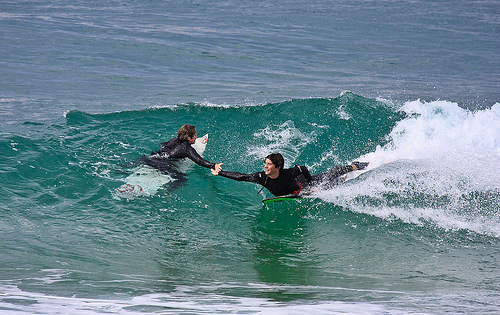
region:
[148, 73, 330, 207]
Surfers high fiving.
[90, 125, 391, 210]
Two surfers passing each other.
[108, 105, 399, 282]
Surfers on the waves.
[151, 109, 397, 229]
Surfer smiling in the water.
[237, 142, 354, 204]
Surfer in a black wet suit.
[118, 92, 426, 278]
Surfer on a wave.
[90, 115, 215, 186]
Surfer on a white surfboard.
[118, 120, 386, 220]
Two surfers hitting each other's hands.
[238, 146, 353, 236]
Surfer on green surfboard.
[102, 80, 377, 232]
Ocean wave.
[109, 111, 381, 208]
Two surfers clasping hands mid-wave.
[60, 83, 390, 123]
The crest of the wave.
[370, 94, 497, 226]
The white water of the wave's crash.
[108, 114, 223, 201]
A surfer straddling a white board.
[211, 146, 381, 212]
A prone surfer extends an arm to a companion.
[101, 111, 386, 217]
Two surfers extend a high five in the middle of a wave.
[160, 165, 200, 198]
The right wave of a surfer's wet suit.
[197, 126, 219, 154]
The surfboard's upturned nose.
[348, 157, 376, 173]
The foot of the surfer coming down with the wave.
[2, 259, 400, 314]
The leftover foam of a crashed wave.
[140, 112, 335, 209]
two people are surfing.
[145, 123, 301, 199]
Two people are in black dress.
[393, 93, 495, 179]
Waves are white color.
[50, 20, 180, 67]
Water is blue color.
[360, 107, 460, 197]
Water is splashing.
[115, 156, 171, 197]
Surfing board is white color.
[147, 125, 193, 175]
Woman is lying on the surfing board.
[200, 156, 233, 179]
Both the people are holding the hands together.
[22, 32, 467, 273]
day time picture.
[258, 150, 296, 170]
Man is wearing black color cap.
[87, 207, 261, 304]
the water is wet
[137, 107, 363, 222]
the kids are swimming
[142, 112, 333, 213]
the kids are wearing black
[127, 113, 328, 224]
the kids are white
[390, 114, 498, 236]
the water has bubbles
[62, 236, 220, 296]
the water is rough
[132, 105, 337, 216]
there is a boy and girl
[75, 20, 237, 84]
the ocean is big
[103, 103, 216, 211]
the girl is surfing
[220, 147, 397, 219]
The boy has a surfboard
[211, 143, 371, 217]
Surfer lying on a surfboard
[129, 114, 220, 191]
Girl sitting on a surfboard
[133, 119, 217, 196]
Girl has long hair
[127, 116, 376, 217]
Boy touch hand of woman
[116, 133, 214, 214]
Surfboard is white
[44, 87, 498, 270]
Wave rolling in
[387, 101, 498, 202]
WAve is white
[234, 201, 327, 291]
Reflection of man in the water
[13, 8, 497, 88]
Water is calm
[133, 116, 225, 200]
Woman wears a black suit